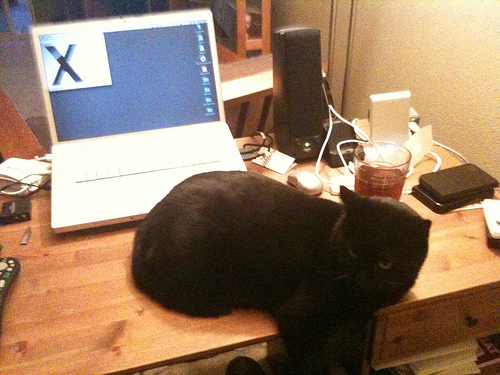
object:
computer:
[27, 7, 247, 238]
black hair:
[293, 209, 325, 269]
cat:
[131, 170, 431, 372]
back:
[155, 170, 340, 207]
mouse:
[287, 169, 323, 196]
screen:
[36, 21, 220, 142]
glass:
[352, 140, 412, 200]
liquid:
[354, 164, 404, 199]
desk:
[0, 144, 500, 374]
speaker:
[273, 27, 320, 158]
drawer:
[379, 286, 500, 363]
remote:
[0, 255, 20, 315]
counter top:
[0, 119, 494, 375]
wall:
[347, 0, 500, 123]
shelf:
[216, 0, 271, 57]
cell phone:
[410, 161, 499, 215]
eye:
[378, 257, 393, 269]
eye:
[345, 245, 361, 258]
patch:
[38, 31, 113, 94]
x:
[42, 41, 84, 87]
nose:
[349, 272, 369, 285]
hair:
[363, 203, 409, 244]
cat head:
[325, 185, 433, 299]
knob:
[463, 313, 481, 328]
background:
[58, 23, 209, 145]